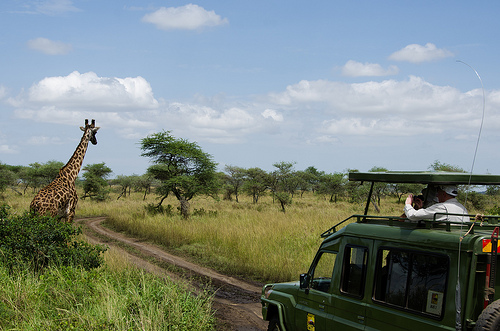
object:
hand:
[405, 194, 413, 205]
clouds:
[1, 69, 280, 148]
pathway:
[79, 211, 280, 331]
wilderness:
[0, 172, 500, 331]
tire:
[478, 300, 500, 331]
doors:
[311, 296, 368, 328]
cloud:
[388, 44, 451, 64]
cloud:
[327, 55, 404, 84]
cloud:
[35, 39, 75, 55]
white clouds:
[340, 35, 450, 112]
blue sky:
[0, 0, 499, 91]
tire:
[265, 320, 278, 330]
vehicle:
[259, 167, 499, 331]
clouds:
[342, 40, 498, 131]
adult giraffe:
[30, 119, 101, 225]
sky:
[0, 0, 500, 178]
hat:
[444, 186, 458, 196]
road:
[74, 215, 268, 331]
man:
[403, 187, 471, 225]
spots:
[31, 139, 88, 216]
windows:
[372, 247, 450, 319]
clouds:
[259, 77, 491, 141]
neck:
[60, 134, 89, 181]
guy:
[403, 187, 469, 225]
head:
[82, 117, 101, 145]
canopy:
[351, 172, 500, 184]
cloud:
[31, 68, 156, 112]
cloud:
[265, 74, 483, 134]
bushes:
[0, 212, 101, 278]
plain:
[0, 171, 488, 331]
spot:
[51, 190, 60, 202]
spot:
[64, 170, 78, 179]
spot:
[69, 150, 79, 160]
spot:
[32, 192, 46, 202]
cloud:
[144, 3, 234, 30]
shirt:
[404, 198, 470, 226]